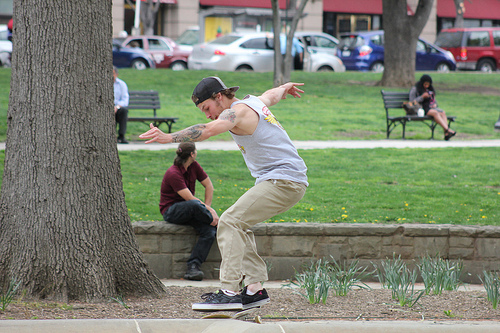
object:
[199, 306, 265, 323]
skateboard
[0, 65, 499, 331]
park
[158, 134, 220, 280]
person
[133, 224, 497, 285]
wall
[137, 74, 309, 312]
skater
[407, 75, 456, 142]
woman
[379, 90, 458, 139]
bench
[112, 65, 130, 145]
man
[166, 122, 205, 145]
tattoo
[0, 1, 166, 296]
tree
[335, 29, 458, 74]
car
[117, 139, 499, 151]
path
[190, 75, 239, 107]
cap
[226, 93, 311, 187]
tank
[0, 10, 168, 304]
trunk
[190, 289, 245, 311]
shoe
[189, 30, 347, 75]
vehicle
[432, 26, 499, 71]
suv